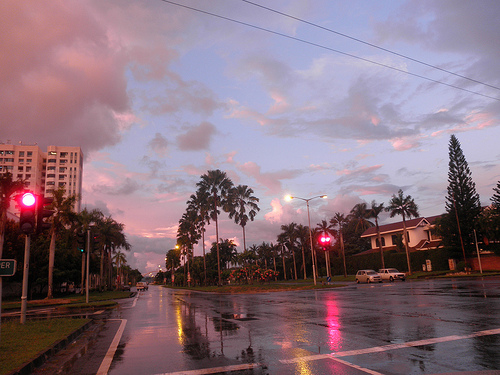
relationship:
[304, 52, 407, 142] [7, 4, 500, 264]
clouds are in sky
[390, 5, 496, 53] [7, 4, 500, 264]
clouds are in sky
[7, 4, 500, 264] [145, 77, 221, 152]
sky has clouds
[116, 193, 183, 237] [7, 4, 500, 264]
clouds are in sky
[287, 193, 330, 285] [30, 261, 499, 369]
light on street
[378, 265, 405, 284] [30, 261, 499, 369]
car on street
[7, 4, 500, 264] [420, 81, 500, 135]
sky has clouds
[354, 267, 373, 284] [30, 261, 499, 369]
car on street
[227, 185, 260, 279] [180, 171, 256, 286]
tree in a group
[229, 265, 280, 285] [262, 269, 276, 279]
plant has flowers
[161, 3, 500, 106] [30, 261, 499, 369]
cables are above street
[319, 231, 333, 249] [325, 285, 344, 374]
light has reflection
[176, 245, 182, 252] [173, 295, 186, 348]
light has reflection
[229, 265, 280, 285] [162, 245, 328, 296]
plant on island